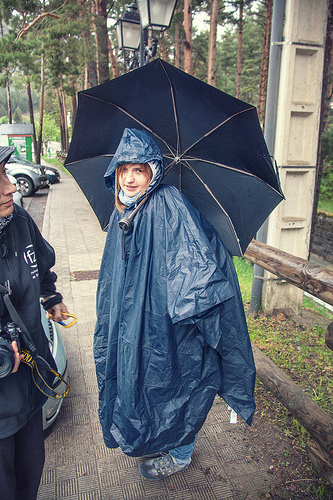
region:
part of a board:
[297, 399, 301, 405]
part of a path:
[235, 452, 240, 463]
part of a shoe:
[181, 471, 186, 480]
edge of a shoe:
[163, 478, 165, 482]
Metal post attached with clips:
[255, 0, 288, 244]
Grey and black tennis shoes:
[135, 457, 198, 481]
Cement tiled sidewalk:
[39, 437, 306, 498]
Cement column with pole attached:
[249, 1, 319, 327]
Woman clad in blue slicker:
[88, 131, 256, 459]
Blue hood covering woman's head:
[98, 127, 163, 201]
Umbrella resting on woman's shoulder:
[61, 62, 288, 259]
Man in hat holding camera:
[0, 139, 79, 403]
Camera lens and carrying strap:
[0, 317, 72, 402]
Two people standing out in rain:
[0, 58, 297, 498]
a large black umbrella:
[62, 62, 290, 271]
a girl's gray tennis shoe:
[137, 459, 193, 478]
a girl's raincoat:
[93, 123, 260, 458]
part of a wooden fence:
[244, 236, 331, 446]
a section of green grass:
[234, 253, 252, 283]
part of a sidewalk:
[43, 175, 114, 317]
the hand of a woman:
[44, 300, 66, 316]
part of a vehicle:
[7, 157, 50, 196]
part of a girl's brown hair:
[107, 161, 150, 210]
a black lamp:
[111, 9, 140, 57]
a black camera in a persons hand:
[0, 322, 77, 401]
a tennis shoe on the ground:
[135, 442, 193, 479]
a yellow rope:
[44, 304, 78, 327]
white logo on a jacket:
[23, 240, 42, 275]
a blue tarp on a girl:
[92, 125, 256, 453]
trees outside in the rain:
[1, 1, 331, 188]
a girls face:
[112, 159, 149, 195]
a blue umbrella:
[65, 56, 272, 260]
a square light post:
[109, 1, 179, 58]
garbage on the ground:
[225, 401, 239, 424]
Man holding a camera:
[0, 280, 77, 402]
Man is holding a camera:
[0, 280, 78, 404]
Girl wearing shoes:
[134, 444, 195, 482]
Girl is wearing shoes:
[127, 434, 196, 478]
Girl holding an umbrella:
[61, 58, 290, 260]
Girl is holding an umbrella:
[59, 56, 287, 260]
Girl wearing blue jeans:
[164, 426, 206, 462]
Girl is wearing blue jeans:
[166, 430, 198, 459]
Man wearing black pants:
[0, 400, 50, 498]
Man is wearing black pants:
[0, 401, 48, 498]